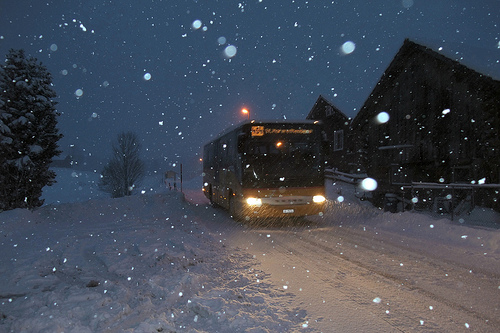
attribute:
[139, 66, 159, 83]
snowflake — small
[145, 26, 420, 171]
snow — falling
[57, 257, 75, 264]
snow — speck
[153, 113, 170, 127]
snow — speck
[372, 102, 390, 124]
snow — speck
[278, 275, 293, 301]
snow — speck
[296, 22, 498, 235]
building — dark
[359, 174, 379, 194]
snowflake — small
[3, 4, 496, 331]
snow — falling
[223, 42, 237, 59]
snowflake — small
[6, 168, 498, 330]
snow — speck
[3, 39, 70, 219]
tree — pine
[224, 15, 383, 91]
sky — snow filled, evening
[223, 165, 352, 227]
headlights — bright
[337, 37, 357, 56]
snowflake — small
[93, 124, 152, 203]
tree — leafless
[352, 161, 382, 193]
snow — falling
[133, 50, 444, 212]
snow — falling